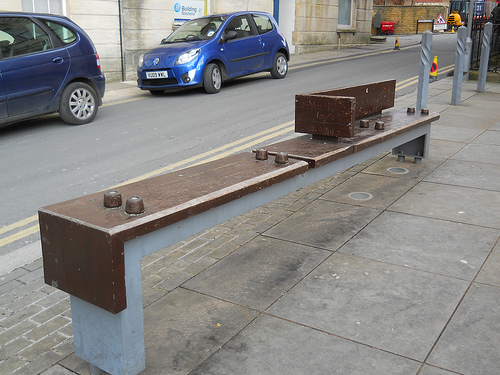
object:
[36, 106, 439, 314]
top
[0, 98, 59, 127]
dirt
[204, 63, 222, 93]
tire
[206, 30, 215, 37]
sticker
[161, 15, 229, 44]
window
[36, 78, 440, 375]
bench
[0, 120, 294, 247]
lines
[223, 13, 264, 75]
door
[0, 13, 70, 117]
door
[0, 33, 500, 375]
road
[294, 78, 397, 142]
seat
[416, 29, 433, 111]
pole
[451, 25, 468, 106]
pole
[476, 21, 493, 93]
pole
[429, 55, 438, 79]
cone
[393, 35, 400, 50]
cone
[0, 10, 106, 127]
blue car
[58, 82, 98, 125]
tire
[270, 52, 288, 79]
tire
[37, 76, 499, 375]
block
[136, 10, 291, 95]
blue car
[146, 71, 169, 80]
number plate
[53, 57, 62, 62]
handle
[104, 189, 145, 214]
knobs